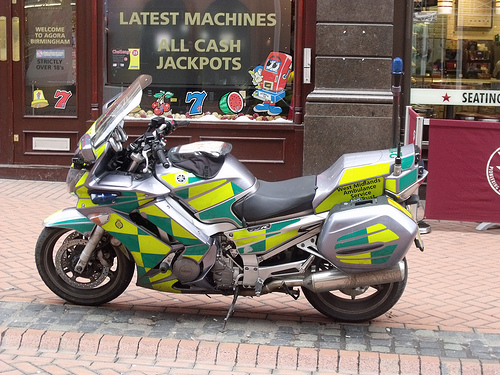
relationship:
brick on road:
[42, 325, 64, 355] [7, 279, 484, 374]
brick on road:
[51, 325, 88, 359] [0, 178, 500, 373]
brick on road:
[96, 336, 120, 361] [0, 178, 500, 373]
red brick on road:
[177, 329, 198, 361] [43, 286, 470, 372]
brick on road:
[449, 259, 469, 268] [0, 178, 500, 373]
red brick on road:
[177, 339, 198, 368] [0, 178, 500, 373]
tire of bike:
[34, 232, 123, 309] [36, 57, 436, 322]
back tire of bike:
[302, 250, 408, 320] [36, 57, 436, 322]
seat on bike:
[230, 171, 323, 228] [36, 57, 436, 322]